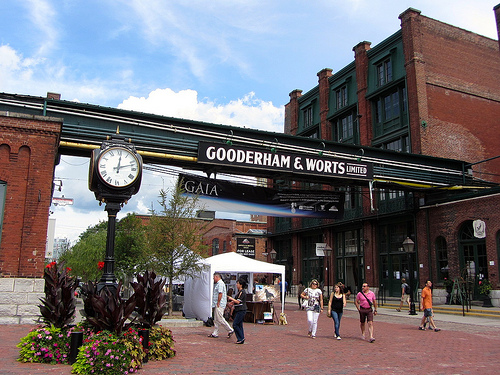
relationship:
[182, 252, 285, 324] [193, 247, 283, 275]
tent has roof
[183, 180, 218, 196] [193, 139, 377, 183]
gaia on sign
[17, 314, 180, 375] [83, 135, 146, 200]
flowers beside clock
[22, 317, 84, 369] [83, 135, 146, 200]
flowers beside clock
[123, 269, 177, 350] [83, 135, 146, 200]
shrub beside clock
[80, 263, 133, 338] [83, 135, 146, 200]
shrub beside clock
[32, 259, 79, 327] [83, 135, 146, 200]
plants beside clock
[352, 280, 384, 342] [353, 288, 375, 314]
man wearing pink shirt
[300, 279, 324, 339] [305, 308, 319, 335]
person wearing white pants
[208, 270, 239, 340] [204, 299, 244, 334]
man wearing pants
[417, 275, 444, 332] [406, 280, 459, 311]
man wearing orange top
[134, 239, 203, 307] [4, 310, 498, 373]
tent on street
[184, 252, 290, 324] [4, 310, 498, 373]
tent on street